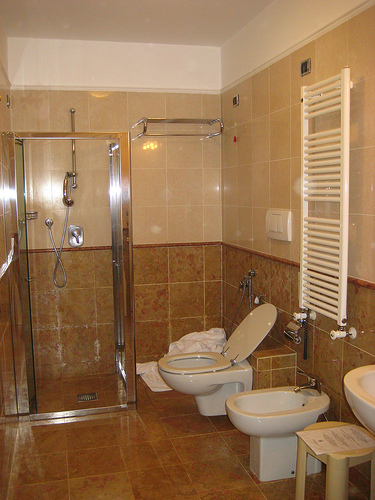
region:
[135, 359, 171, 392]
White towels on bathroom floor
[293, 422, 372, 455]
Piece of paper on a stool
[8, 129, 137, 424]
Silver framed shower stall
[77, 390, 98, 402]
Drain in shower stall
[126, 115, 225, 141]
Silver towel bar in bathroom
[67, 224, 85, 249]
Water control handle in shower stall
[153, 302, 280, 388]
White toilet with open lid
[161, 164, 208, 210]
Square bathroom wall tile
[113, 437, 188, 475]
Light brown floor tile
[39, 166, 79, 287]
Adjustable spray hose in shower stall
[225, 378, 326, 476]
a beige color bide in the bathroom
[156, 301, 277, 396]
a beige toilet in the bathroom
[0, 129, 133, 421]
a clear shower stall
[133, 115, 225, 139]
a metal towel rack and hanger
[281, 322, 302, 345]
a toilet roll dispenser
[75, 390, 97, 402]
the shower drain grate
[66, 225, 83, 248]
the shower on and off water valve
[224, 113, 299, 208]
beige bathroom tiles on the wall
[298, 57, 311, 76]
air vents on the wall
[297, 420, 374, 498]
a beige plastic stool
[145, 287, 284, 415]
the lid of a toilet is up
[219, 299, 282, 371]
lid of a toilet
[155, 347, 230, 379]
sit of toilet is plastic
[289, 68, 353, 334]
a window in front a toilet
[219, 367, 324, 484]
a sink on the floor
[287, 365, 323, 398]
faucet of sink is silver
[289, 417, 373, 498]
a white paper over a stool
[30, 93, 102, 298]
a shower in a bathroom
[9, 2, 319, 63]
ceiling of bathroom is white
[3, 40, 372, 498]
a tiled bathroom with a shower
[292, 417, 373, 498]
a plastic stool is in the bathroom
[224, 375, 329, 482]
a white porcelain bidet is in the bathroom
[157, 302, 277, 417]
a toilet is on the wall in the bathroom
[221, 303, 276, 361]
the lid of the toilet is up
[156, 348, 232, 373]
the toilet seat is down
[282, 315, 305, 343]
the toilet paper holder is on the wall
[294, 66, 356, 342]
a towel warmer rack is on the wall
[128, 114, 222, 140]
a towel holder rack is in the bathroom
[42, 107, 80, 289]
a hand sprayer is in the shower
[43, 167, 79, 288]
a shower head and chrome hose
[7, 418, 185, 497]
part of the bathroom floor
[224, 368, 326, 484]
a white bidet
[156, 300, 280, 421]
a white toilet with the lid up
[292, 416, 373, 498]
a plastic stool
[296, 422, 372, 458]
a piece of paper with black words on it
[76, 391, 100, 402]
a silver shower drain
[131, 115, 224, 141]
a chrome high up shelf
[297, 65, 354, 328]
a white shutter towel rack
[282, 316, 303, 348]
an empty chrome toilet paper holder